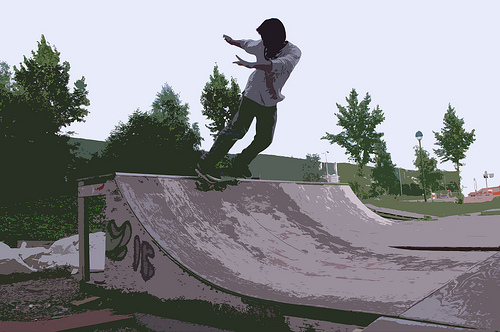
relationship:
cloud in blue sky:
[0, 0, 500, 159] [0, 1, 498, 170]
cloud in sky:
[0, 0, 500, 159] [7, 9, 498, 204]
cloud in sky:
[61, 37, 138, 94] [7, 9, 498, 204]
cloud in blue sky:
[0, 0, 500, 159] [73, 10, 210, 53]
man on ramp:
[191, 13, 302, 178] [72, 165, 498, 330]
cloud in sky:
[0, 0, 500, 159] [349, 14, 426, 109]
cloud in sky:
[0, 0, 500, 159] [334, 19, 448, 73]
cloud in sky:
[0, 0, 500, 159] [82, 5, 205, 74]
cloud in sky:
[0, 0, 500, 159] [4, 5, 496, 172]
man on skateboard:
[191, 13, 302, 178] [191, 155, 256, 191]